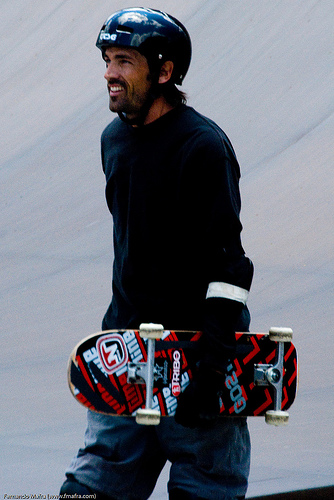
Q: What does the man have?
A: A skateboard.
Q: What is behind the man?
A: A half pipe.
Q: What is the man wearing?
A: A black shirt.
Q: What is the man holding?
A: A skateboard.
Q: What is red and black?
A: The skateboard.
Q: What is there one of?
A: Skateboard.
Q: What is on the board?
A: Wheels.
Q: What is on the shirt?
A: White stripe.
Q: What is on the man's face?
A: Beard.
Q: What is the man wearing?
A: Jeans.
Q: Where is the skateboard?
A: Man's hand.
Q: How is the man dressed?
A: Jeans and sweatshirt.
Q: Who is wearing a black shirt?
A: The man.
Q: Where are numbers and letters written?
A: Skateboard.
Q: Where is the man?
A: Skate Park.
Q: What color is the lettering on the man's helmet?
A: White.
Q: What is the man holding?
A: A skateboard.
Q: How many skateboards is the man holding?
A: One.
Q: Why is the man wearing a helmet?
A: Because he could get hurt.